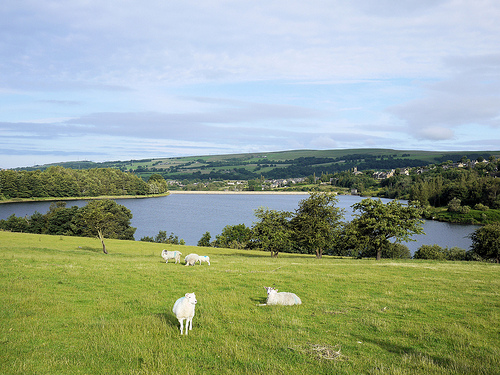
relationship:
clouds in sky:
[165, 33, 477, 121] [3, 0, 496, 161]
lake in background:
[0, 190, 486, 252] [4, 146, 498, 263]